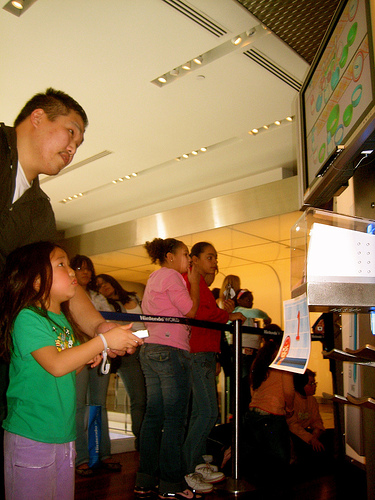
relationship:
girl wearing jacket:
[186, 241, 243, 485] [180, 264, 231, 354]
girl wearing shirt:
[0, 239, 145, 498] [1, 305, 84, 444]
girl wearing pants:
[0, 239, 145, 498] [0, 427, 76, 498]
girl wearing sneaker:
[134, 238, 199, 499] [161, 488, 199, 498]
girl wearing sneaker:
[134, 238, 199, 499] [131, 481, 159, 497]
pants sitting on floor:
[4, 427, 77, 500] [67, 436, 334, 498]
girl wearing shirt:
[134, 238, 199, 499] [136, 261, 201, 332]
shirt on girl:
[7, 298, 95, 456] [2, 239, 120, 497]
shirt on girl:
[137, 262, 194, 354] [32, 297, 107, 432]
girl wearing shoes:
[134, 236, 204, 498] [132, 483, 203, 499]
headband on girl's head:
[235, 289, 244, 301] [41, 252, 74, 303]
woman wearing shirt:
[52, 250, 116, 498] [79, 282, 115, 322]